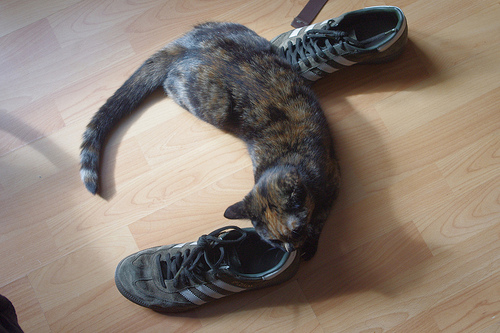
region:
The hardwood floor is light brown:
[358, 108, 498, 324]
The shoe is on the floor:
[109, 219, 306, 311]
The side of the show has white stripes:
[174, 278, 248, 306]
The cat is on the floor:
[72, 15, 345, 262]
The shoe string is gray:
[198, 223, 248, 274]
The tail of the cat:
[76, 58, 168, 196]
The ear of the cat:
[269, 161, 307, 206]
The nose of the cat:
[281, 239, 298, 253]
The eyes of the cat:
[261, 222, 313, 247]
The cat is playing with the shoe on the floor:
[40, 21, 499, 315]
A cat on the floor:
[76, 18, 343, 264]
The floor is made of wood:
[1, 2, 499, 330]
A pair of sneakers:
[114, 4, 410, 317]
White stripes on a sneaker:
[179, 277, 246, 310]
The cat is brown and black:
[77, 22, 343, 263]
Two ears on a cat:
[222, 179, 310, 221]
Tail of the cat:
[78, 44, 164, 199]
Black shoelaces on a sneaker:
[153, 224, 248, 288]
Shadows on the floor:
[175, 40, 447, 300]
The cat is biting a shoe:
[78, 21, 344, 316]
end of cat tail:
[72, 136, 112, 201]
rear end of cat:
[161, 24, 228, 116]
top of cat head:
[231, 158, 314, 223]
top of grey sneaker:
[105, 252, 152, 306]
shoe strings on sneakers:
[179, 252, 209, 278]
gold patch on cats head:
[261, 210, 288, 233]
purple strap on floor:
[285, 0, 335, 25]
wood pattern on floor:
[394, 174, 446, 225]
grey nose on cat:
[282, 242, 295, 254]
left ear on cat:
[217, 195, 252, 229]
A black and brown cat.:
[80, 20, 345, 258]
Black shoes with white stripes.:
[112, 16, 407, 308]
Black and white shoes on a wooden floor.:
[11, 3, 487, 328]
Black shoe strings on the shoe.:
[150, 225, 241, 287]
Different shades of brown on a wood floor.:
[10, 40, 482, 326]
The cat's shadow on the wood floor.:
[292, 75, 448, 308]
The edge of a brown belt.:
[288, 0, 323, 27]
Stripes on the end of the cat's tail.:
[78, 131, 103, 192]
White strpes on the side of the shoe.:
[177, 280, 240, 300]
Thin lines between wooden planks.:
[1, 5, 493, 332]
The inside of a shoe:
[245, 243, 265, 265]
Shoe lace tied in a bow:
[207, 228, 233, 263]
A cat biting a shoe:
[224, 203, 305, 263]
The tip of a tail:
[80, 145, 100, 191]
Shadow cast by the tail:
[105, 140, 111, 191]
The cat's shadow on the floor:
[340, 156, 355, 241]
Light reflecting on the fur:
[173, 64, 183, 96]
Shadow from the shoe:
[363, 66, 388, 76]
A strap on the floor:
[305, 7, 314, 17]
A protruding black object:
[1, 302, 10, 332]